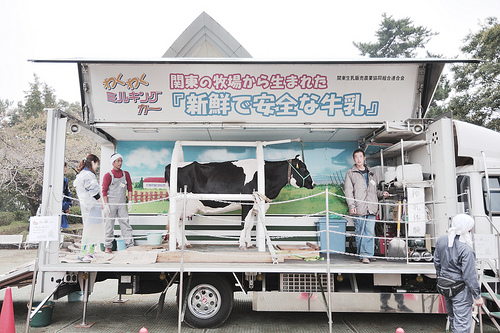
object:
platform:
[38, 236, 437, 275]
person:
[63, 161, 72, 228]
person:
[72, 150, 112, 262]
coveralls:
[103, 169, 133, 248]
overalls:
[102, 169, 132, 247]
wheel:
[176, 273, 234, 329]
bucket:
[26, 301, 55, 328]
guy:
[344, 149, 389, 263]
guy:
[433, 214, 484, 333]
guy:
[101, 152, 134, 255]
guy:
[72, 154, 105, 263]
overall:
[344, 163, 383, 258]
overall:
[433, 234, 481, 318]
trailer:
[27, 59, 499, 329]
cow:
[165, 153, 316, 251]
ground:
[430, 131, 439, 146]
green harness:
[286, 159, 311, 186]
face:
[291, 158, 316, 190]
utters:
[182, 208, 199, 221]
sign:
[83, 60, 422, 125]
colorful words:
[100, 72, 405, 117]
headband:
[109, 152, 123, 165]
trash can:
[314, 213, 348, 255]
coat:
[344, 163, 386, 216]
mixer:
[341, 146, 381, 255]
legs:
[175, 208, 188, 244]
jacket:
[72, 169, 104, 246]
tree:
[354, 8, 499, 131]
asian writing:
[80, 61, 421, 125]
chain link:
[45, 192, 448, 265]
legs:
[239, 206, 254, 246]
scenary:
[115, 140, 367, 228]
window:
[482, 174, 500, 217]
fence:
[126, 191, 170, 204]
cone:
[0, 287, 20, 332]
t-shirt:
[445, 213, 474, 248]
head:
[447, 214, 475, 247]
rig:
[27, 46, 485, 333]